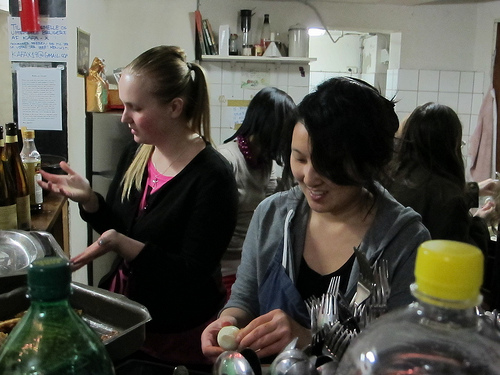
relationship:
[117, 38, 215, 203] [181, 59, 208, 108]
blonde hair in pony tail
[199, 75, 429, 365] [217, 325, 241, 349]
girl peeling egg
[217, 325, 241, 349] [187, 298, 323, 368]
egg in hands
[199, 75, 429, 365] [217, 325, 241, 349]
girl holding egg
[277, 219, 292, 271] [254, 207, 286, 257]
string on jacket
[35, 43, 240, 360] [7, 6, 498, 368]
blonde cooking in kitchen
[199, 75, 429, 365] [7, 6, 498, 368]
girl cooking in kitchen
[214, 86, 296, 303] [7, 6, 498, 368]
lady cooking in kitchen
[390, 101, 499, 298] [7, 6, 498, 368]
lady cooking in kitchen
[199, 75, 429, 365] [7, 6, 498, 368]
girl standing in kitchen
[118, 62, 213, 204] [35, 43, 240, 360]
pony tail on blonde